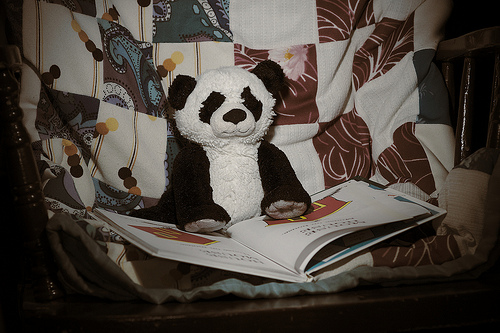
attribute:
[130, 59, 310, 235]
teddy bear — reading, black, white, stuffed, panda bear, panda, nose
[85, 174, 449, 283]
book — opened, large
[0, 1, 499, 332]
chair — brown, wooden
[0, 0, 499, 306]
quilt — patches, squares, square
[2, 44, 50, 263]
arm — wooden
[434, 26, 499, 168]
arm — wooden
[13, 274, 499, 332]
seat — brown, wooden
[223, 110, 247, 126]
nose — black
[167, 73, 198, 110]
ear — black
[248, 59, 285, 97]
ear — black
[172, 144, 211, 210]
arms — black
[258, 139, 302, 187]
arms — black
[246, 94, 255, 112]
eye — black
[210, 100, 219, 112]
eye — black